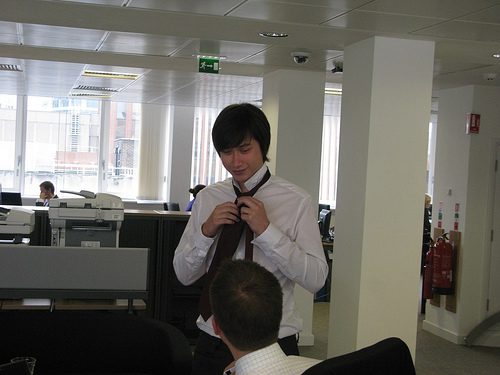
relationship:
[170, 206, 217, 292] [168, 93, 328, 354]
arm of a person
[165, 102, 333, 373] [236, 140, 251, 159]
person has eye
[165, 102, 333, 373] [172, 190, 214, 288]
person has arm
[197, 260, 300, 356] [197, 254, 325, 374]
head on person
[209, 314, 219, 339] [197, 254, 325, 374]
ear on person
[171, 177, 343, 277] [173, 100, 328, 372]
shirt on man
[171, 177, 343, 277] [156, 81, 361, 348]
shirt on man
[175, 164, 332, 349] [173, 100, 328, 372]
dress shirt on man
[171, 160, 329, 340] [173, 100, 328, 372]
white shirt on man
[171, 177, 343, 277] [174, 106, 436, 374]
shirt on man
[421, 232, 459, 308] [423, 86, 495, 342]
fire hydrant on wall